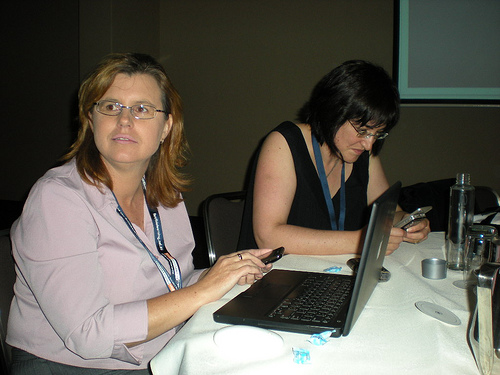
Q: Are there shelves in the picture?
A: No, there are no shelves.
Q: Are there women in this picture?
A: Yes, there is a woman.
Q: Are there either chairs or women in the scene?
A: Yes, there is a woman.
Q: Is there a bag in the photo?
A: No, there are no bags.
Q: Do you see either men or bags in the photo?
A: No, there are no bags or men.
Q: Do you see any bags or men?
A: No, there are no bags or men.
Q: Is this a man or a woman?
A: This is a woman.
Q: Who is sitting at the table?
A: The woman is sitting at the table.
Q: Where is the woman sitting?
A: The woman is sitting at the table.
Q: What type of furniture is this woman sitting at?
A: The woman is sitting at the table.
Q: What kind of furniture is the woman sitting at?
A: The woman is sitting at the table.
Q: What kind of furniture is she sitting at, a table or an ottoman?
A: The woman is sitting at a table.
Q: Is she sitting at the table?
A: Yes, the woman is sitting at the table.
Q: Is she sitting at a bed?
A: No, the woman is sitting at the table.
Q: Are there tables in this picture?
A: Yes, there is a table.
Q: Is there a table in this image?
A: Yes, there is a table.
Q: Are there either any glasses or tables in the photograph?
A: Yes, there is a table.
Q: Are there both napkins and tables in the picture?
A: No, there is a table but no napkins.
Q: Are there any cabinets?
A: No, there are no cabinets.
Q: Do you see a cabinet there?
A: No, there are no cabinets.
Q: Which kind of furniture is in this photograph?
A: The furniture is a table.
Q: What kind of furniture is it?
A: The piece of furniture is a table.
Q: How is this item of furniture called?
A: That is a table.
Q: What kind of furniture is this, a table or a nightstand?
A: That is a table.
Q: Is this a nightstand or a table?
A: This is a table.